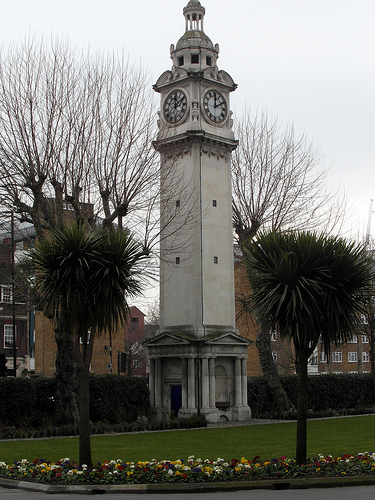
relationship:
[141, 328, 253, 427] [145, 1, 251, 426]
base of tower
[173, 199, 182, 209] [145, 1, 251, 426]
windows on tower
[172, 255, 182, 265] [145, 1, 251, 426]
windows on tower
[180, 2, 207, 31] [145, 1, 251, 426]
cupola on tower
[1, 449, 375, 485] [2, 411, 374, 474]
flowers near grass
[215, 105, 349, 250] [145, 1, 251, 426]
branches near tower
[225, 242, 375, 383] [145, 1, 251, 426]
buildings near tower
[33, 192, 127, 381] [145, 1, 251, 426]
buildings near tower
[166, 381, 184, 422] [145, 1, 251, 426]
entrance of tower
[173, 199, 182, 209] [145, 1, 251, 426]
windows of tower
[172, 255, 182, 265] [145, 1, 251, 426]
windows of tower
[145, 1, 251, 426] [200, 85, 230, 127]
tower has clock face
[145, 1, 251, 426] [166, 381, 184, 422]
tower as entrance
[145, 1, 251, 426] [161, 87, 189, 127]
tower has clock face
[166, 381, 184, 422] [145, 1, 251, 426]
entrance on tower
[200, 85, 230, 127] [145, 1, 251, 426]
clock face on tower